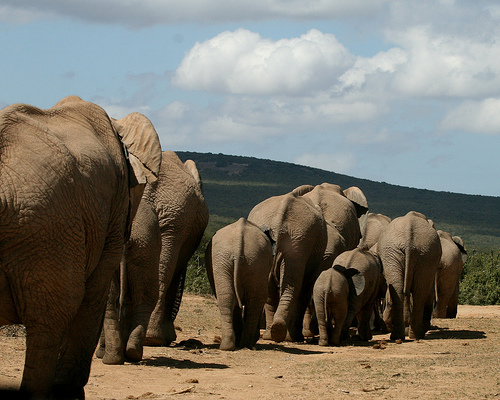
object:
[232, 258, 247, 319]
tail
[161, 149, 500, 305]
hill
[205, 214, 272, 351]
elephant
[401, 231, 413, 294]
tail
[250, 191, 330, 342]
elephant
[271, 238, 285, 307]
tail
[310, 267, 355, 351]
elephant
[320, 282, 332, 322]
tail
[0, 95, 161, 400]
elephant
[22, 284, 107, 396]
leg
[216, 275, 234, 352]
leg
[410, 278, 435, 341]
leg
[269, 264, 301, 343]
leg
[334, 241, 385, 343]
elephant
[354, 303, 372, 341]
leg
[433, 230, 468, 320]
elephant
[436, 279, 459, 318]
leg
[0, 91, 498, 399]
landscape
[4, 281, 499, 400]
terrain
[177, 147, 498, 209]
mountain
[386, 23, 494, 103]
clouds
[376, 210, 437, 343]
elephants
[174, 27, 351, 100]
cloud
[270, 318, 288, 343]
bottom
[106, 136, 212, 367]
elephant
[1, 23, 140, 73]
blue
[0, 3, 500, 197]
blue sky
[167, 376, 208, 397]
rocks